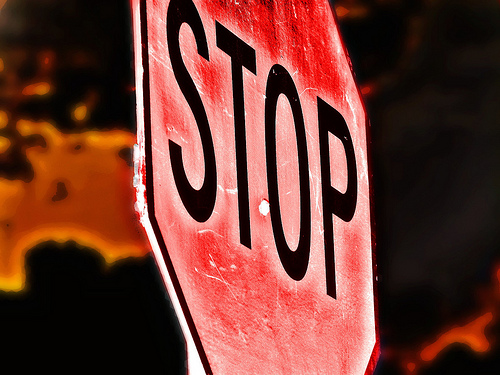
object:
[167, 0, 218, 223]
black s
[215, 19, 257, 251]
black t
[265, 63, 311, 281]
black o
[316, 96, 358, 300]
black p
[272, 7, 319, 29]
bright red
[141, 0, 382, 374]
black line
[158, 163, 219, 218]
black and orange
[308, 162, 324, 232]
scratches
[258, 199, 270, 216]
hole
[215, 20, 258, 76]
thick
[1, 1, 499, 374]
background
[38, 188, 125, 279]
orange and black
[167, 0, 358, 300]
stop sign